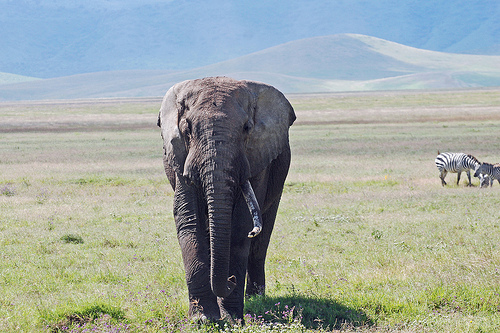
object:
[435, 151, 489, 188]
zebras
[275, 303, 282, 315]
flowers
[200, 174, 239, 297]
trunk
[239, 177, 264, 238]
tusk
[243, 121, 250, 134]
eyes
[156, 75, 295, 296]
head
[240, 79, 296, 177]
ear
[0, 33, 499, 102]
dune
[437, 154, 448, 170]
stripes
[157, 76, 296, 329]
elephant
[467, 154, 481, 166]
mane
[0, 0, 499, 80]
mountains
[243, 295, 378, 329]
shadow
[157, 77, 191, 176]
ear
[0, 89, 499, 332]
field